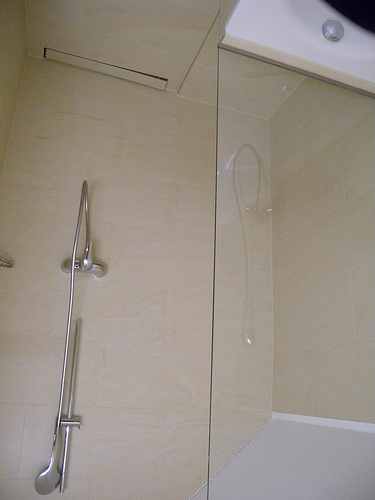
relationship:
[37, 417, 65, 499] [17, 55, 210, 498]
head next to wall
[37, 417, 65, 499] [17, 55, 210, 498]
head on side of wall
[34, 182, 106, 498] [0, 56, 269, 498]
head on side of wall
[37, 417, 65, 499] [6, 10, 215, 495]
head on side of wall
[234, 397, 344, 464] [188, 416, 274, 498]
part on a line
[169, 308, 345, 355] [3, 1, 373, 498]
part of a glass